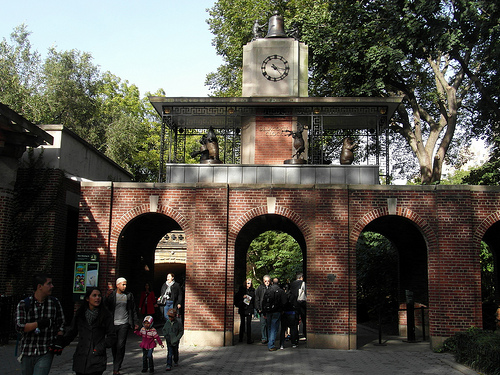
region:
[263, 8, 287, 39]
metal bell on a monument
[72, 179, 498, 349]
four brick archways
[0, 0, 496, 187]
trees standing behind wall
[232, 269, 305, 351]
people standing in brick archway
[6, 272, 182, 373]
people walking on stone path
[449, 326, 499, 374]
bushes growing beside stone path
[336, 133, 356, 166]
metal animal statue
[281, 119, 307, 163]
bronze statue of a horse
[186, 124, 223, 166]
a bronze statue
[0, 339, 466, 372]
a stone path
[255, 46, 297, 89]
clock on the top of the building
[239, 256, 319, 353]
people standing in the brick arch way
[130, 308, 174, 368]
child in a patterned pink coat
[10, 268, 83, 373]
man wearing a plaid button down shirt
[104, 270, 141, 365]
man wearing a tight white hat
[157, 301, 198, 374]
little boy wearing orange baseball cap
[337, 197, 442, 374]
large brick walkway over the sidewalk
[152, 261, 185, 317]
woman wearing a open black cardigan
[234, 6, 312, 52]
bell on top of the clock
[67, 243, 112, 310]
informational sign on brick building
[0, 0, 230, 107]
blue of daytime sky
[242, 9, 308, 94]
metal bell on structure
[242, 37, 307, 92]
clock on stone structure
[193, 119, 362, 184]
metal sculptures on platform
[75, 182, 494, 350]
brick structure with arches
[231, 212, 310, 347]
people walking through arches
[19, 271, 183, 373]
adults and children walking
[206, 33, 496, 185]
green leaves on tree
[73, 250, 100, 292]
sign on brick structure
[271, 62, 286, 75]
hands on clock face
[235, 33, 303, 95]
a clock on a small tower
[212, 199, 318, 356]
an archway in a brick structure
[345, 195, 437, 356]
an archway in a brick structure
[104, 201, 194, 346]
an archway in a brick structure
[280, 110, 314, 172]
a statue of a deer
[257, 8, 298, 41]
a bell on top of a tower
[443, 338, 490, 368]
a clump of bushes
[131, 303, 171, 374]
a little girl in pink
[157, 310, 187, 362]
a boy in a sweatshirt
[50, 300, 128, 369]
a woman in an overcoat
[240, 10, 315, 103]
top of stone clock tower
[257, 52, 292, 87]
black clock on tower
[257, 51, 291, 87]
clock that reads three twenty two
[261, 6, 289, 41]
bell on top of clock area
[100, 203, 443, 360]
row of arched doorways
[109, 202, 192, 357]
first arched doorway in row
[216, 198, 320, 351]
second arched doorway in row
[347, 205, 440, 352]
third arched doorway in row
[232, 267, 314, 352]
people walking through arched doorway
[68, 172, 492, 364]
brick wall with arched doorways